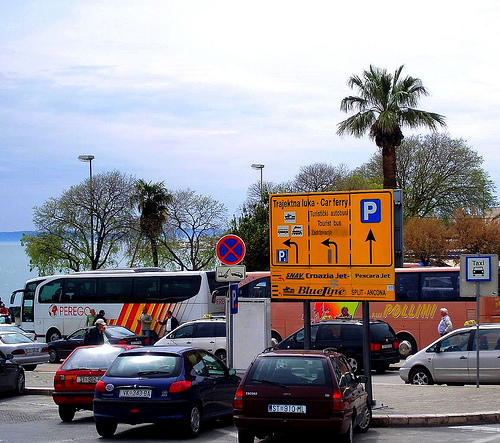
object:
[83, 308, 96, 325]
people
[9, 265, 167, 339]
bus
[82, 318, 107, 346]
man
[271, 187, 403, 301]
sign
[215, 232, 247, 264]
sign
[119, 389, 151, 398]
license plate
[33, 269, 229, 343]
perego bus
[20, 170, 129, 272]
tree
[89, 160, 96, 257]
light pole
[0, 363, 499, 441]
road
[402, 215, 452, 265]
trees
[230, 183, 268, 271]
tree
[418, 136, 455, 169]
leaves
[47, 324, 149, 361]
car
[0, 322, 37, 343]
car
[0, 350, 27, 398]
car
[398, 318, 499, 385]
minivan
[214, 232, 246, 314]
traffic sign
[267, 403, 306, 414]
license plate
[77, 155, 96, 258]
street lamp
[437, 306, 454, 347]
man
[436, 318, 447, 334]
belly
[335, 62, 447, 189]
palm tree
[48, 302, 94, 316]
word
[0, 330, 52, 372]
car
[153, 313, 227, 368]
car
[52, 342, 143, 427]
car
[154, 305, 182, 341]
man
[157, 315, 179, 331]
jacket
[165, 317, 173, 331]
shirt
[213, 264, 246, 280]
tow sign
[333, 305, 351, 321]
man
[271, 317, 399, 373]
mini van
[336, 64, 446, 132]
fronds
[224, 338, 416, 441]
car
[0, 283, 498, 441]
parking lot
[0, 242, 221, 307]
ocean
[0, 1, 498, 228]
sky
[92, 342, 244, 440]
car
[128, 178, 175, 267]
palm tree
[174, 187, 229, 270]
trees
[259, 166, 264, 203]
pole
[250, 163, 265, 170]
light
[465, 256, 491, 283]
taxi sign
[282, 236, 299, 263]
arrows